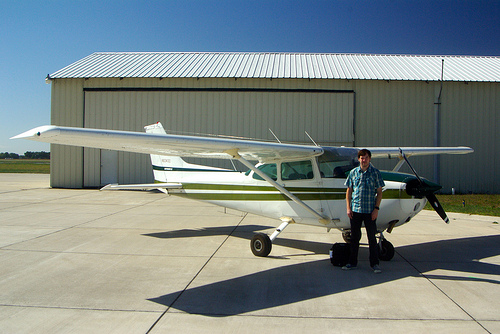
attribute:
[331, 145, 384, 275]
man — posing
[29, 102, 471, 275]
plane — white, small, motionless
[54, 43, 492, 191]
hangar — metal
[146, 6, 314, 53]
sky — clear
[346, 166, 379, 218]
shirt — blue, plaid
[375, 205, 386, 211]
watch — black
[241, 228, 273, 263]
wheel — small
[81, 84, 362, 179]
door — large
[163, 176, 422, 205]
stripes — green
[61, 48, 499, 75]
roof — metal, white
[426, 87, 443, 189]
pipe — metal